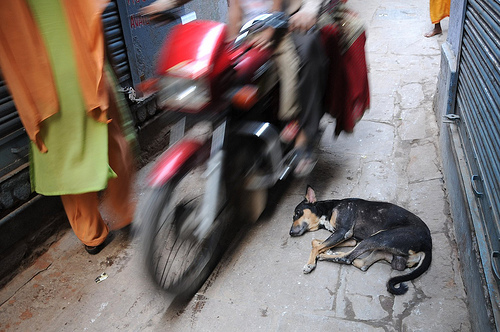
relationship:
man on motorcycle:
[131, 0, 326, 174] [136, 9, 371, 313]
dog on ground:
[289, 184, 433, 298] [0, 0, 497, 332]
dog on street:
[289, 184, 433, 298] [0, 0, 497, 332]